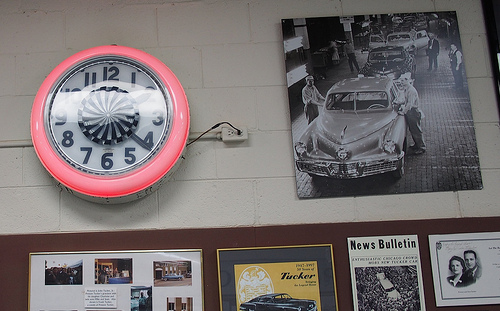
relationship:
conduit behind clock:
[1, 125, 248, 149] [29, 44, 191, 205]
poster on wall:
[278, 9, 484, 200] [7, 5, 496, 227]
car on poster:
[294, 69, 416, 181] [278, 9, 484, 200]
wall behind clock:
[8, 2, 298, 217] [29, 44, 191, 205]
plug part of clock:
[212, 115, 265, 160] [40, 17, 178, 213]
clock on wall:
[29, 44, 191, 205] [80, 5, 262, 43]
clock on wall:
[22, 30, 209, 210] [0, 1, 498, 304]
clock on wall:
[29, 44, 191, 205] [7, 5, 496, 227]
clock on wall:
[29, 44, 191, 205] [0, 1, 498, 304]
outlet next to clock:
[222, 126, 248, 142] [3, 40, 261, 227]